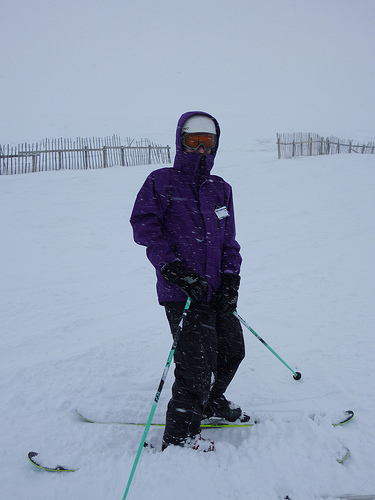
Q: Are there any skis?
A: Yes, there are skis.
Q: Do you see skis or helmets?
A: Yes, there are skis.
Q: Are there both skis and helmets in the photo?
A: Yes, there are both skis and a helmet.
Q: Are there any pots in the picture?
A: No, there are no pots.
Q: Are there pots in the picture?
A: No, there are no pots.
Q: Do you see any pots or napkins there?
A: No, there are no pots or napkins.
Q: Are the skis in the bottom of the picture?
A: Yes, the skis are in the bottom of the image.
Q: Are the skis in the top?
A: No, the skis are in the bottom of the image.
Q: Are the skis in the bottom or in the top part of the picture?
A: The skis are in the bottom of the image.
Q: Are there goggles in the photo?
A: Yes, there are goggles.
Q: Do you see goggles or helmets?
A: Yes, there are goggles.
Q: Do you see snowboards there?
A: No, there are no snowboards.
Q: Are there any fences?
A: Yes, there is a fence.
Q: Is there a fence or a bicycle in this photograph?
A: Yes, there is a fence.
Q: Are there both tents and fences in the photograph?
A: No, there is a fence but no tents.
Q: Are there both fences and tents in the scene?
A: No, there is a fence but no tents.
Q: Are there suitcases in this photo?
A: No, there are no suitcases.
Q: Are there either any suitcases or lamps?
A: No, there are no suitcases or lamps.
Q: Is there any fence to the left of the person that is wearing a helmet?
A: Yes, there is a fence to the left of the person.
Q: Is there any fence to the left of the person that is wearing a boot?
A: Yes, there is a fence to the left of the person.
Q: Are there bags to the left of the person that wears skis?
A: No, there is a fence to the left of the person.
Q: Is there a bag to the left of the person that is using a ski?
A: No, there is a fence to the left of the person.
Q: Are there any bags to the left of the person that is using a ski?
A: No, there is a fence to the left of the person.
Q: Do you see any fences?
A: Yes, there is a fence.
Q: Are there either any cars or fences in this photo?
A: Yes, there is a fence.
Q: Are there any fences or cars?
A: Yes, there is a fence.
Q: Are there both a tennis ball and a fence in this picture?
A: No, there is a fence but no tennis balls.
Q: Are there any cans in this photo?
A: No, there are no cans.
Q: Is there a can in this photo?
A: No, there are no cans.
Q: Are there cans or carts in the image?
A: No, there are no cans or carts.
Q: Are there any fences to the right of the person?
A: Yes, there is a fence to the right of the person.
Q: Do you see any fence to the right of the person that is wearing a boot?
A: Yes, there is a fence to the right of the person.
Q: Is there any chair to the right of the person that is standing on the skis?
A: No, there is a fence to the right of the person.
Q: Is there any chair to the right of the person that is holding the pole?
A: No, there is a fence to the right of the person.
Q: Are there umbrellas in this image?
A: No, there are no umbrellas.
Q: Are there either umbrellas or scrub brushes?
A: No, there are no umbrellas or scrub brushes.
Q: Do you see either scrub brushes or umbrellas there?
A: No, there are no umbrellas or scrub brushes.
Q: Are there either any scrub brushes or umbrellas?
A: No, there are no umbrellas or scrub brushes.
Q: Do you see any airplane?
A: No, there are no airplanes.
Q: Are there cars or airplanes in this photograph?
A: No, there are no airplanes or cars.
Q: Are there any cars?
A: No, there are no cars.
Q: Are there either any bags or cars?
A: No, there are no cars or bags.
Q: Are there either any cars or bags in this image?
A: No, there are no cars or bags.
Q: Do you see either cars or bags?
A: No, there are no cars or bags.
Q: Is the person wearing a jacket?
A: Yes, the person is wearing a jacket.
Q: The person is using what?
A: The person is using a ski.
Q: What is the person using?
A: The person is using a ski.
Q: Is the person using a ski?
A: Yes, the person is using a ski.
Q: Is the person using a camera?
A: No, the person is using a ski.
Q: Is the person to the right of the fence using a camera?
A: No, the person is using a ski.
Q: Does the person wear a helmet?
A: Yes, the person wears a helmet.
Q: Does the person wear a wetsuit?
A: No, the person wears a helmet.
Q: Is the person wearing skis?
A: Yes, the person is wearing skis.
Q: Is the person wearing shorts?
A: No, the person is wearing skis.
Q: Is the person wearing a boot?
A: Yes, the person is wearing a boot.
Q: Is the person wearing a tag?
A: Yes, the person is wearing a tag.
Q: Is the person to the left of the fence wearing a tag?
A: Yes, the person is wearing a tag.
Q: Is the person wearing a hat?
A: No, the person is wearing a glove.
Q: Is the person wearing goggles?
A: Yes, the person is wearing goggles.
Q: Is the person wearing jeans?
A: No, the person is wearing goggles.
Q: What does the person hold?
A: The person holds the pole.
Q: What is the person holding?
A: The person is holding the pole.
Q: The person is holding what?
A: The person is holding the pole.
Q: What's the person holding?
A: The person is holding the pole.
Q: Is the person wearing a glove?
A: Yes, the person is wearing a glove.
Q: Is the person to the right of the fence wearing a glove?
A: Yes, the person is wearing a glove.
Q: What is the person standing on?
A: The person is standing on the skis.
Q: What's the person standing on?
A: The person is standing on the skis.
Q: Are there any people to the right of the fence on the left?
A: Yes, there is a person to the right of the fence.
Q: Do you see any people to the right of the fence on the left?
A: Yes, there is a person to the right of the fence.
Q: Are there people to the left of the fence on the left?
A: No, the person is to the right of the fence.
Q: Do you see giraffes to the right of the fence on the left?
A: No, there is a person to the right of the fence.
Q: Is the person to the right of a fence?
A: Yes, the person is to the right of a fence.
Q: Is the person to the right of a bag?
A: No, the person is to the right of a fence.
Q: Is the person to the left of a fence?
A: No, the person is to the right of a fence.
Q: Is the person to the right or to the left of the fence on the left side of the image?
A: The person is to the right of the fence.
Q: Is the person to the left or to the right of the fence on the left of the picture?
A: The person is to the right of the fence.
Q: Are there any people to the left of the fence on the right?
A: Yes, there is a person to the left of the fence.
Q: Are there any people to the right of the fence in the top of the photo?
A: No, the person is to the left of the fence.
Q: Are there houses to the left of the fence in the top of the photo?
A: No, there is a person to the left of the fence.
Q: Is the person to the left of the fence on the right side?
A: Yes, the person is to the left of the fence.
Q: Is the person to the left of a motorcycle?
A: No, the person is to the left of the fence.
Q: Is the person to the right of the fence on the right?
A: No, the person is to the left of the fence.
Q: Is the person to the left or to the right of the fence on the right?
A: The person is to the left of the fence.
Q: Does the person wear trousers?
A: Yes, the person wears trousers.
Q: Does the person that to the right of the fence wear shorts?
A: No, the person wears trousers.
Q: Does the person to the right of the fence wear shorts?
A: No, the person wears trousers.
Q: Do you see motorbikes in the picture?
A: No, there are no motorbikes.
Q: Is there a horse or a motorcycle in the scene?
A: No, there are no motorcycles or horses.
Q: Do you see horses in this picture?
A: No, there are no horses.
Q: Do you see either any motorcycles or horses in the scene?
A: No, there are no horses or motorcycles.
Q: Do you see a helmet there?
A: Yes, there is a helmet.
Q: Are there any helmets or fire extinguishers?
A: Yes, there is a helmet.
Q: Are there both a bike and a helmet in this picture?
A: No, there is a helmet but no bikes.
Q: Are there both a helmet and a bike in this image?
A: No, there is a helmet but no bikes.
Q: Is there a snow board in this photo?
A: No, there are no snowboards.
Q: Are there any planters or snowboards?
A: No, there are no snowboards or planters.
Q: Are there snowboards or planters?
A: No, there are no snowboards or planters.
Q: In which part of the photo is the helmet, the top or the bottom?
A: The helmet is in the top of the image.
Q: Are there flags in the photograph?
A: No, there are no flags.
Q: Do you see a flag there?
A: No, there are no flags.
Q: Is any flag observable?
A: No, there are no flags.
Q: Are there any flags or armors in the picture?
A: No, there are no flags or armors.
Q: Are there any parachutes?
A: No, there are no parachutes.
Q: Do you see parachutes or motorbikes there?
A: No, there are no parachutes or motorbikes.